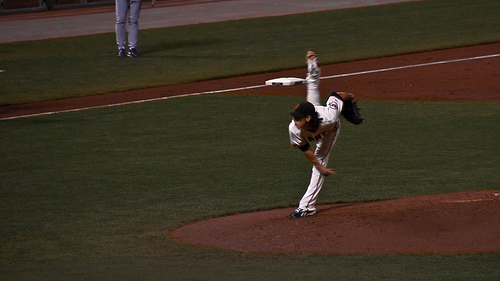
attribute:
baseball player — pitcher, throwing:
[285, 49, 366, 218]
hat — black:
[288, 101, 315, 117]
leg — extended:
[305, 48, 321, 109]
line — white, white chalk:
[0, 51, 500, 128]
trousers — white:
[297, 129, 340, 210]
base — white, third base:
[266, 76, 307, 85]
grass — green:
[1, 94, 497, 200]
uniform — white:
[286, 72, 344, 206]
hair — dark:
[310, 109, 322, 130]